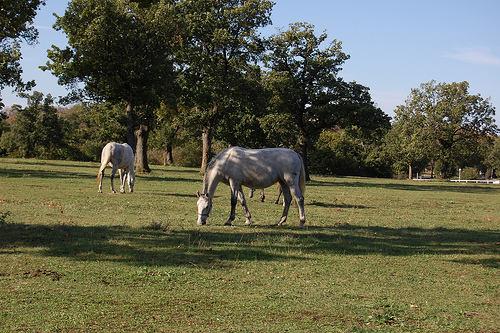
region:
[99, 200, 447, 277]
shadow of the tree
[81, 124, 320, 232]
white horses eating grass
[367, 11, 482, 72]
sky blue with clouds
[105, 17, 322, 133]
trees with branches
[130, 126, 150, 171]
trunk of the tree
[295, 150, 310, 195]
tail of the horse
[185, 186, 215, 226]
head of the horse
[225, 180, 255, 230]
legs of the white color horse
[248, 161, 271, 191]
belly of the horse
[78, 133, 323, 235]
two horses eating grass in field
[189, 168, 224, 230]
horses neck and head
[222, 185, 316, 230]
four legs of horse eating grass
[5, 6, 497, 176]
green leafy trees near horse pasture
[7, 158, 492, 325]
green grass of pasture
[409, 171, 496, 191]
white fence near the pasture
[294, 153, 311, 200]
horses tail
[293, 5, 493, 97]
clear blue skies above the pasture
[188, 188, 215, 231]
horses head while eating green grass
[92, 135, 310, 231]
there are three white horses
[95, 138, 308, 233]
horses are in a field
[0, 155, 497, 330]
the grass is light green and mowed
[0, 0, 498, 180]
the sky is blue with few clouds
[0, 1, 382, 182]
trees behind horses in field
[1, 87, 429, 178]
row of trees in grove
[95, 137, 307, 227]
horses are grazing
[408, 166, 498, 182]
white fences in background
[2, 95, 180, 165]
brown leaves in the row of trees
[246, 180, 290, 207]
horses legs on hidden horse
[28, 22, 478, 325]
Some horses are out in the field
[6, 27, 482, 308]
The horses are on a big ranch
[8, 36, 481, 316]
The horses are eating the grass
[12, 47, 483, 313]
Some horses are getting some nutrition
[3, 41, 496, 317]
The horses are out of their stable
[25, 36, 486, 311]
The horses are out in the sunshine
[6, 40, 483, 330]
Some horses are out in the daytime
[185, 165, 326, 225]
horse eating the grass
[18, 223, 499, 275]
shadows on the lawn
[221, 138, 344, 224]
reflections on the horse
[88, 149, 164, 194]
second horse bending down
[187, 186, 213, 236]
face of horse is white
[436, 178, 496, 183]
bench in the background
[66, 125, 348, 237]
two horses eating the grass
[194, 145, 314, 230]
White horse is grazing in the field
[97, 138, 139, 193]
white horse stands in field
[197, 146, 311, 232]
white horse stands in field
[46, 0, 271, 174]
tree behind white horse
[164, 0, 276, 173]
tree behind white horse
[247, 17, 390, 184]
tree behind white horse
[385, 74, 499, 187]
tree behind white horse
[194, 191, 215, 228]
head belongs to horse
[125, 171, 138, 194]
head belongs to horse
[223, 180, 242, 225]
leg belongs to white horse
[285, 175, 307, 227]
leg belongs to white horse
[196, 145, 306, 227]
the horse is grazing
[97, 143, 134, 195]
the horse is grazing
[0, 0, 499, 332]
the blue sky above the green grass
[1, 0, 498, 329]
the trees on the grass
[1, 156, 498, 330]
the shadows on the grass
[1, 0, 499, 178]
the green trees under the blue sky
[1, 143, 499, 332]
the horses grazing on the grass